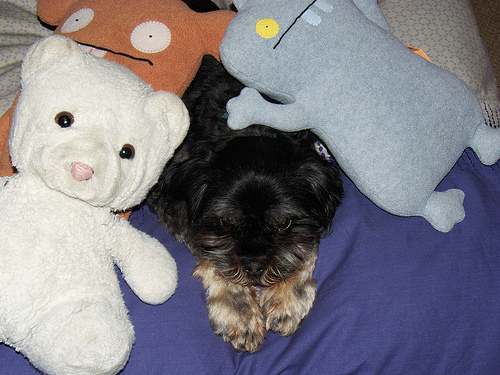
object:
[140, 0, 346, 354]
dog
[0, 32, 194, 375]
stuffed animal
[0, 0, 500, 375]
bed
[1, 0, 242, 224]
stuffed animal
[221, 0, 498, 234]
stuffed animal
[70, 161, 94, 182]
nose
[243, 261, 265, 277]
nose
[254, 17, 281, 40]
eye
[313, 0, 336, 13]
tooth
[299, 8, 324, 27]
tooth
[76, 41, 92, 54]
tooth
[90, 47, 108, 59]
tooth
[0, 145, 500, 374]
blanket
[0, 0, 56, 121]
pillow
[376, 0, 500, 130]
pillow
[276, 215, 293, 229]
eye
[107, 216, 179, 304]
arm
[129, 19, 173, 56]
eye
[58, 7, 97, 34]
eye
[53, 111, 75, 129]
eye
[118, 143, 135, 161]
eye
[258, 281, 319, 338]
paw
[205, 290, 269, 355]
paw